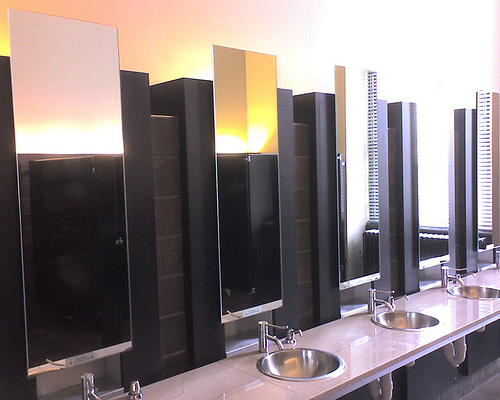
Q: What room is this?
A: Bathroom.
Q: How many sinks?
A: 3.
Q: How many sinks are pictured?
A: 4.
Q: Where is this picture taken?
A: Bathroom.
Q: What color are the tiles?
A: Black.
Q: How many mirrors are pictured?
A: 5.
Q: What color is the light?
A: Yellow.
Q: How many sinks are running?
A: 0.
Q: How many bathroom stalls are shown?
A: 3.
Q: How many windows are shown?
A: 1.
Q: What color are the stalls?
A: Black.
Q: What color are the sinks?
A: Silver.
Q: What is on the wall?
A: Mirrors.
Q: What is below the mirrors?
A: A sink.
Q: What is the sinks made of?
A: Steel.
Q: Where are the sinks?
A: In the countertop.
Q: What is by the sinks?
A: Faucets.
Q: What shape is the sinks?
A: Round.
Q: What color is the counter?
A: White.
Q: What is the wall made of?
A: Tile.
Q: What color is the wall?
A: Brown.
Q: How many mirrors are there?
A: 5.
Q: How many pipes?
A: Two.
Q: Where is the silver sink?
A: In bathroom.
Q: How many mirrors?
A: Five.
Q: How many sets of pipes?
A: Two.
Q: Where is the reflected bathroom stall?
A: In the mirrors.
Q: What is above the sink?
A: A mirror.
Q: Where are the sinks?
A: In the bathroom.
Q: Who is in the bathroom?
A: No One.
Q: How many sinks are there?
A: Four.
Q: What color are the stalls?
A: Black.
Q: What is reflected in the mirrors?
A: Bathroom stalls.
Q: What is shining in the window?
A: Sunlight.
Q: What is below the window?
A: Radiator.